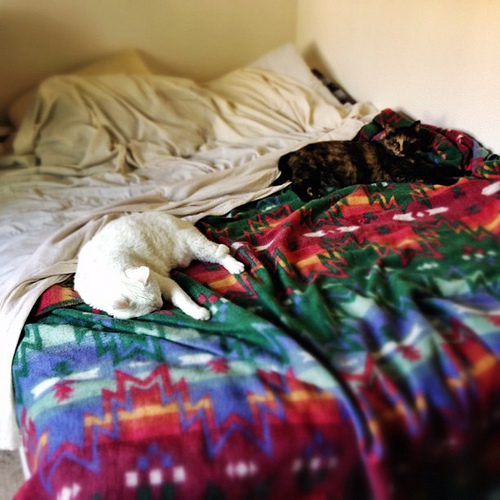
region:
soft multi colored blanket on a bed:
[249, 185, 494, 494]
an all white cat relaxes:
[69, 202, 248, 322]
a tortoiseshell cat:
[271, 114, 464, 199]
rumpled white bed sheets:
[8, 65, 279, 243]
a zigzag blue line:
[37, 385, 304, 475]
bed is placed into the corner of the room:
[218, 13, 417, 149]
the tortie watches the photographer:
[377, 111, 430, 169]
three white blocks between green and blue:
[120, 455, 191, 498]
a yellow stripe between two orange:
[109, 380, 366, 433]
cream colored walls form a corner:
[107, 0, 492, 43]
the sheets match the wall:
[155, 65, 457, 107]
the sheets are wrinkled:
[110, 135, 237, 190]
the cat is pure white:
[51, 208, 253, 328]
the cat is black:
[268, 110, 459, 197]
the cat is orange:
[266, 117, 469, 198]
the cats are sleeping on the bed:
[64, 115, 456, 312]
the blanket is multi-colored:
[45, 387, 258, 489]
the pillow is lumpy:
[34, 59, 334, 138]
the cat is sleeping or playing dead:
[62, 203, 257, 337]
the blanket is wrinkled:
[294, 281, 371, 397]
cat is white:
[42, 179, 287, 367]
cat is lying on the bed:
[60, 198, 262, 343]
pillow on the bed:
[224, 58, 340, 151]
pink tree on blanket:
[48, 375, 90, 406]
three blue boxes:
[131, 439, 185, 472]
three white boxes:
[119, 466, 199, 488]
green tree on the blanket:
[38, 360, 81, 382]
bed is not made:
[69, 112, 371, 251]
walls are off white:
[378, 32, 468, 114]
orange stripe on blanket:
[110, 401, 192, 430]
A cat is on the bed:
[46, 192, 272, 359]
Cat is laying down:
[42, 187, 281, 349]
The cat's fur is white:
[51, 200, 273, 345]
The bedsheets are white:
[7, 78, 316, 205]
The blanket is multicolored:
[36, 185, 496, 499]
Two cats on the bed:
[54, 108, 470, 349]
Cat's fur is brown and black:
[261, 104, 476, 216]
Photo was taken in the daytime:
[0, 0, 495, 496]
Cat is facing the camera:
[367, 115, 432, 161]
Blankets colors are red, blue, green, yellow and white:
[26, 221, 498, 498]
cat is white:
[77, 187, 234, 333]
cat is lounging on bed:
[47, 188, 267, 329]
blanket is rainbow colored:
[54, 111, 498, 476]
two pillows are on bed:
[22, 46, 334, 186]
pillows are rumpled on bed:
[46, 28, 363, 182]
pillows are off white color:
[9, 49, 334, 175]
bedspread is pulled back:
[21, 125, 328, 303]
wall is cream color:
[299, 0, 492, 132]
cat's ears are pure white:
[124, 265, 151, 311]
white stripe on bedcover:
[300, 195, 497, 236]